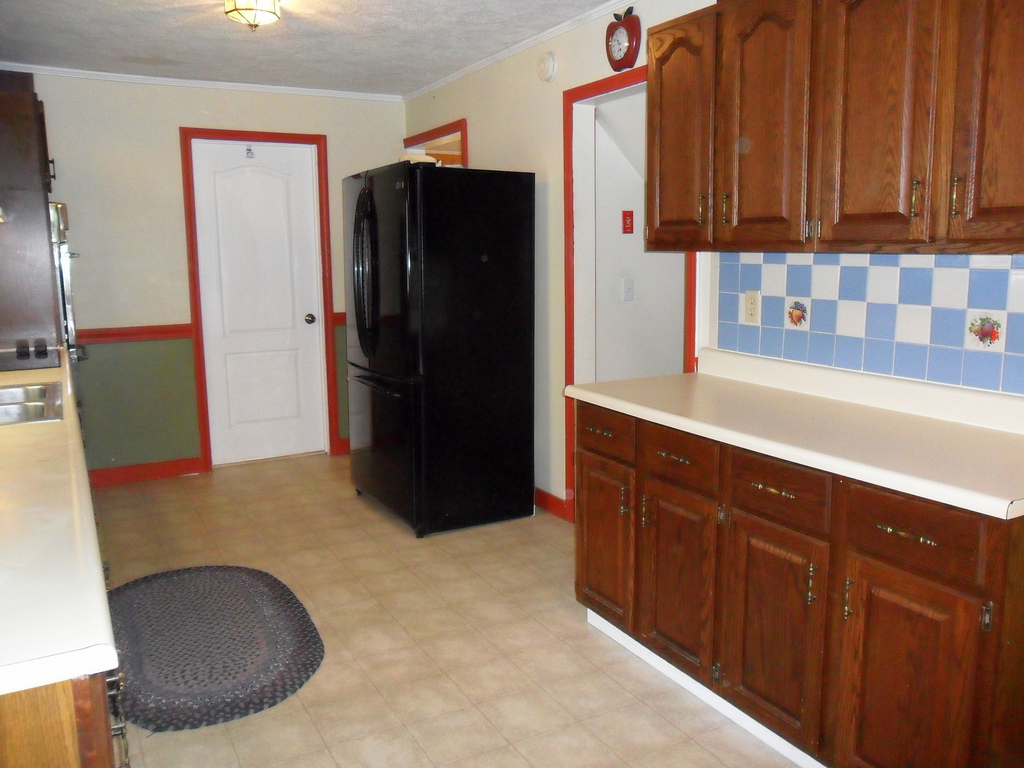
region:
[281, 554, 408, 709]
A person eating a orange.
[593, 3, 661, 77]
an apple clock above a doorway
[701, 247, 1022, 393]
blue and white tile backsplash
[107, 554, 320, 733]
a blue braided rug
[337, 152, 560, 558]
a black refridgerator and freezer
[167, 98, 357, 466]
red trim around a white door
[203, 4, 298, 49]
a light on the ceiling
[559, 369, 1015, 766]
lower level kitchen cupboards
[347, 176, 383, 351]
handles on a refridgerator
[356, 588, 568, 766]
tile flooring in a kitchen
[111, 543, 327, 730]
Grey rug on the tile.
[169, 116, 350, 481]
Red trimming around the door.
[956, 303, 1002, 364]
Red flower on a white towel.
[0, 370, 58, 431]
Silver sink in the counter.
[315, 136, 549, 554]
Black refrigerator against the wall.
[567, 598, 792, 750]
White paneling up under the counter.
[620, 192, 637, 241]
Red frame around the light switch.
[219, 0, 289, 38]
Light coming down from the ceiling.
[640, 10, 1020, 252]
Set of wooden cabinets above the tile.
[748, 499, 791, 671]
a brown cabinet door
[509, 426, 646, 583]
a brown cabinet door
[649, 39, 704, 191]
a brown cabinet door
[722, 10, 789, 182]
a brown cabinet door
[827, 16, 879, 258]
a brown cabinet door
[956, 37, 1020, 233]
a brown cabinet door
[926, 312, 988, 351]
a blue tile on the wall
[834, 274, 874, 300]
a blue tile on the wall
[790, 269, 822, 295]
a blue tile on the wall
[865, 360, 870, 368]
a blue tile on the wall